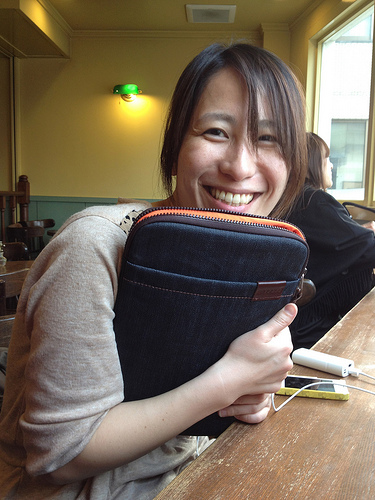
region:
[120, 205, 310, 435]
a tablet protective case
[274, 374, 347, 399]
a cellular phone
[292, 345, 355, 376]
a cellular battery charger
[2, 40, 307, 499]
a woman sitting at a table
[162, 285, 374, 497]
a worn brown table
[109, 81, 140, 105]
a wall light with green shade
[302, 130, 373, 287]
a woman sitting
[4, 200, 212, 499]
a light brown blouse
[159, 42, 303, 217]
a woman's smiling face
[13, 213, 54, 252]
a brown wooden chair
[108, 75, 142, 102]
a green hooded light on the wall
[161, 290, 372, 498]
a worn wooden table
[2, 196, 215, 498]
a gray shirt on a woman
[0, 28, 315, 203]
a yellow painted wall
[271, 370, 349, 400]
a smartphone on a table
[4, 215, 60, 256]
a brown wooden chair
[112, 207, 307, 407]
a blue denim covered book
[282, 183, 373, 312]
a black poncho on a woman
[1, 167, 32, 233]
a brown wood rail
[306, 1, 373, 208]
a window in a room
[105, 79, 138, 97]
green cover on light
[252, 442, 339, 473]
brown color on desk surface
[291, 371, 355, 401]
yellow and white smart phone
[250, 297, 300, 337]
thumb on blue book folder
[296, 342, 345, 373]
white remote on table top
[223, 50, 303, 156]
hair in woman's face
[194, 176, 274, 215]
large grin on woman's face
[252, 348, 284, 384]
veins in woman's hand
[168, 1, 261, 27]
white vent in ceiling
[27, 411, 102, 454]
sleeve on white shirt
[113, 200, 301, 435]
a blue and orange bag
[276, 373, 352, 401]
a yellow cell phone cover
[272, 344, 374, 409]
white cord to a cell phone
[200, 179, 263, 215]
woman's teeth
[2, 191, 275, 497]
a light brown sweater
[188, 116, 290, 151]
a woman's brown eyes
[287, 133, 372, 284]
a woman sitting at the table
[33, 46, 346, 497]
woman sitting at the table holding a bag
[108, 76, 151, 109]
a green light on the wall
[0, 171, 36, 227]
wooden banister on the wall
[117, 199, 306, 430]
Tablet or small computer case being held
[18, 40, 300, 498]
Woman holding a tablet case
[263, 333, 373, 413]
White portable charger charging an iphone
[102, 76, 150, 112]
Green lamp shade on a lamp in room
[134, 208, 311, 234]
Orange interior lining of an electronics case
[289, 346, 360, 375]
White portable charger resting on a wood table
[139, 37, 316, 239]
The face of a woman of asian descent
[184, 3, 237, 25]
Air conditioning vent in the roof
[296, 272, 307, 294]
Zipper on a electronics case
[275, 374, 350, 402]
White iphone with a yellow case